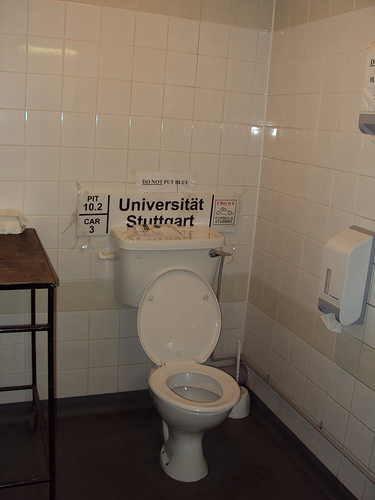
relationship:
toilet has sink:
[121, 285, 268, 480] [114, 216, 231, 256]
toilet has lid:
[121, 285, 268, 480] [136, 260, 223, 345]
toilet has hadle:
[121, 285, 268, 480] [199, 244, 232, 265]